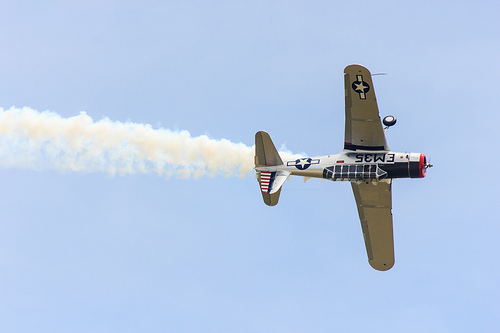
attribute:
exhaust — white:
[41, 135, 214, 168]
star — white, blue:
[294, 155, 321, 172]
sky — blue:
[62, 6, 448, 65]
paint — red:
[420, 155, 424, 170]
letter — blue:
[390, 153, 398, 166]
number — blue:
[356, 152, 360, 164]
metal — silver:
[337, 178, 343, 181]